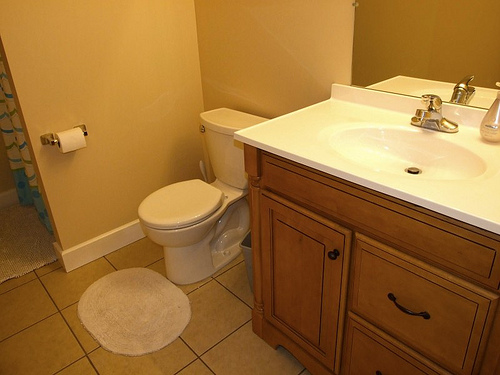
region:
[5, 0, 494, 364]
a bathroom in area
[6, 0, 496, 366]
the bathroom is very nice and clean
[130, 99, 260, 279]
a toilet in the bathroom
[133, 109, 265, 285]
the toilet is white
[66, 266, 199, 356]
a rug infront of the toilet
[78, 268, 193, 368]
the rug is white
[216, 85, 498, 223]
the sink in the bathroom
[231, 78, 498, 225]
the sink is white and clean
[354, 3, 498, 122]
part of the bathroom mirror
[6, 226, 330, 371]
the tan bathroom floor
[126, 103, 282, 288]
White toilet in a bathroom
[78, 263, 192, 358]
White bath rug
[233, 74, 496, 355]
Batrhoom vanity with sink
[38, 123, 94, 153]
Toilet paper holder and roll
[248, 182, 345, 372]
Wooden cabinet vanity door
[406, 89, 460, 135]
Silver bathroom sink faucet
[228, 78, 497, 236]
White bathroom countertop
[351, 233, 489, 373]
Wooden bathroom vanity drawer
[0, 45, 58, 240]
Blue and white shower curtain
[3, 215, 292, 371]
Beige square tile bathroom floor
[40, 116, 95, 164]
there is toilet paper in the holder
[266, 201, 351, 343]
the cabinet is brown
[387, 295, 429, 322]
the handle is black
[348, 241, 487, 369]
the drawer is a rectangle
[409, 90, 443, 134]
the faucet is silver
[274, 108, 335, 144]
the counter is white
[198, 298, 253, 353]
the floor is tile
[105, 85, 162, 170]
the wall is beige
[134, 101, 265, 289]
a toilet sitting in the corner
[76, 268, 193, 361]
the rug sitting in front of the toilet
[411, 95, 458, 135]
the faucet next to the sink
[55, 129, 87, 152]
a roll of toilet paper next to the toilet paper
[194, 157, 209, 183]
the handle of the toilet brush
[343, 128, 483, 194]
the bathroom sink in the counter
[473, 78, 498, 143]
a bottle of hand soap by the faucet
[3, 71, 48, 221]
the shower curtain next to the wall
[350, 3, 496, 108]
the mirror above the sink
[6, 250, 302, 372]
the tile floor of the bathroom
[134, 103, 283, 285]
White toilet next to the wall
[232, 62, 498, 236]
White sink on the bathroom cabinet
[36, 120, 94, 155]
White toilet tissue hanging on the wall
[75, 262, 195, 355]
toilet mat in front of the toilet bowl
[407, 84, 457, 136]
Silver faucet on the sink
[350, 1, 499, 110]
Mirror hanging on the wall behind the sink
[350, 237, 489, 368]
Drawer of the bathroom cabinet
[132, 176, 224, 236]
toilet cover of the toilet bowl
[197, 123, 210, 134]
flush mechanism of the toilet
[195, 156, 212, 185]
Toilet brush next to the toilet bowl